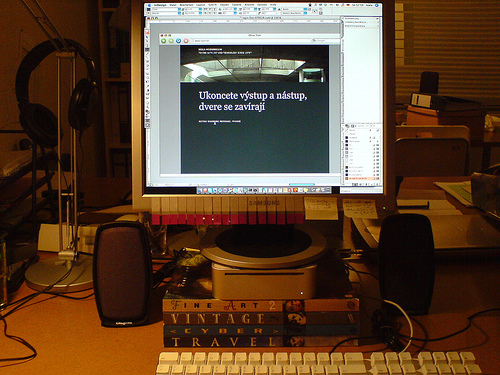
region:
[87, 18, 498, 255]
a computer monitor turned on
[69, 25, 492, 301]
a computer monitor on a desk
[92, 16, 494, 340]
a monitor on a desk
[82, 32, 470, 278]
a monitor turned on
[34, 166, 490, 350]
two computer speakers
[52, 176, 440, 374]
two black computer speakers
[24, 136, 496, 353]
two speakers on a desk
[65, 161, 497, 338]
two computer speakers on a desk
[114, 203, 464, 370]
books under a monitor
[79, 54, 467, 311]
books under a computer monitor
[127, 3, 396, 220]
Silver desktop computer screen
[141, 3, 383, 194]
Open browser on a computer screen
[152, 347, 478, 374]
White computer keyboard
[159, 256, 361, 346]
Stack of four books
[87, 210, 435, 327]
Two black computer speakers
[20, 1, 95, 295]
Flexible metal arm of a lamp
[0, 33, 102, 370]
Corded headphones hanging from the arm of a lamp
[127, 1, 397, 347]
Computer screen resting on top of a stack of books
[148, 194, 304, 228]
Row of sticky tabs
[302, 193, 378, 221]
Two yellow sticky notes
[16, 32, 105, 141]
the headphones are black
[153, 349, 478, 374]
the keyboard is white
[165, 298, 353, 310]
book about Fine Art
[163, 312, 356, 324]
a book called "Vintage"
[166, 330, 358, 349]
a book about travel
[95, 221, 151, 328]
the speaker is black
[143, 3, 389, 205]
the computer is square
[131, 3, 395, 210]
the monitor is on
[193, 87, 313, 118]
the display is not English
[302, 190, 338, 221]
post-it note on the computer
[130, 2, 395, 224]
silver computer monitor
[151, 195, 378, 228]
sticky notes at the bottom of monitor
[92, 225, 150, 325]
black speaker on the left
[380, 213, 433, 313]
black speaker on the right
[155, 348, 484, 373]
top part of white keyboard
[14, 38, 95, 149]
large black headphones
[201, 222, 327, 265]
circular base of monitor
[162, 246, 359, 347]
stack of books under computer monitor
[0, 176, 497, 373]
cluttered surface of table top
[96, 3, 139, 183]
part of bookcase in the back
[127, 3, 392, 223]
computer screen with windows open and active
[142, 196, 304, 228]
line of small paper tabs along bottom of screen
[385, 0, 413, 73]
paper tabs line the right side of computer screen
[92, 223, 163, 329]
left side speaker for computer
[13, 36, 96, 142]
black headphones are hung up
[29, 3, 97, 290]
long metal light is used as headphone rest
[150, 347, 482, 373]
white keyboard on computer desk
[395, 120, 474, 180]
folder organizer behind computer screen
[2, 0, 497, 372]
desk is very cluttered with lots of items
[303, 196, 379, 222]
two rectangle sticky notes with writing upon them